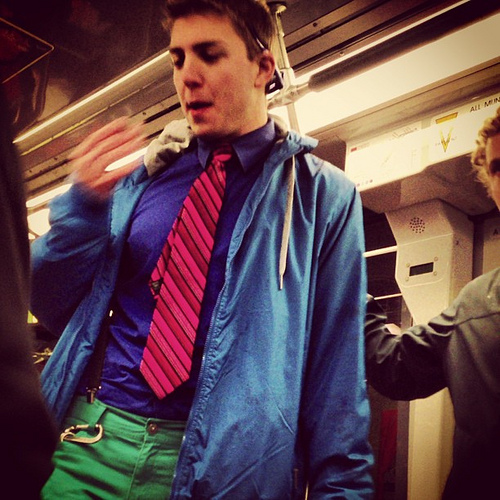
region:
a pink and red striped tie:
[145, 135, 230, 398]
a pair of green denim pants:
[39, 389, 186, 496]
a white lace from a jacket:
[280, 159, 296, 288]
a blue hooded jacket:
[36, 122, 371, 497]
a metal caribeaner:
[62, 426, 103, 444]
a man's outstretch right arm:
[361, 292, 444, 403]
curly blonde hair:
[466, 111, 498, 187]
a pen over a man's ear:
[251, 32, 283, 87]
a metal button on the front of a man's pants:
[146, 418, 156, 434]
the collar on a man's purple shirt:
[195, 117, 279, 166]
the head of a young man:
[142, 1, 263, 142]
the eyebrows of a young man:
[157, 31, 228, 49]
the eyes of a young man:
[158, 45, 229, 75]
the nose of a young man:
[180, 65, 207, 95]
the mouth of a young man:
[182, 86, 222, 121]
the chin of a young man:
[188, 115, 226, 136]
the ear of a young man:
[248, 46, 282, 91]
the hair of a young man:
[231, 16, 271, 48]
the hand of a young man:
[71, 126, 139, 187]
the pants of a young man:
[68, 401, 190, 499]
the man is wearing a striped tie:
[136, 154, 272, 380]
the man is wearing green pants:
[58, 398, 144, 491]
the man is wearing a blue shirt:
[135, 175, 352, 495]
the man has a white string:
[239, 143, 327, 403]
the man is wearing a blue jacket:
[232, 292, 455, 464]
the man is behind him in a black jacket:
[398, 268, 493, 438]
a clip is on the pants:
[56, 413, 145, 490]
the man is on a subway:
[67, 82, 464, 354]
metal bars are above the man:
[20, 64, 255, 272]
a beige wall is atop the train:
[327, 108, 492, 221]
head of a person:
[152, 0, 296, 155]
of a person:
[464, 108, 498, 232]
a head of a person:
[132, 0, 284, 139]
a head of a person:
[434, 90, 498, 237]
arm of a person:
[344, 267, 442, 381]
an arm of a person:
[329, 270, 420, 374]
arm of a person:
[0, 185, 156, 319]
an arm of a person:
[25, 195, 151, 300]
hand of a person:
[70, 109, 157, 193]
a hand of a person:
[64, 95, 169, 206]